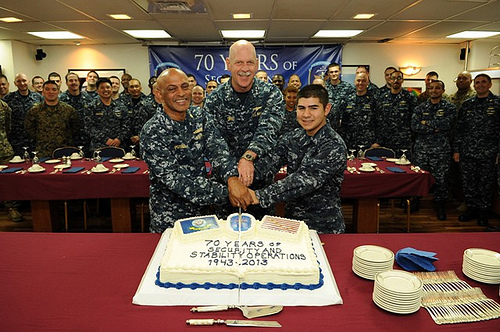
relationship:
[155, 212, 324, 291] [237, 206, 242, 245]
cake cut with knife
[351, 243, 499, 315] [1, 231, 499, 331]
dishes on table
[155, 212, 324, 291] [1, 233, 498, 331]
cake on tablecloth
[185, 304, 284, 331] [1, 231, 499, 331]
knives on table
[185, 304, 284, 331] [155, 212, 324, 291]
knives for cake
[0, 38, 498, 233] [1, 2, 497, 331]
men in photo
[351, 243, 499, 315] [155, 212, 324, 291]
dishes for cake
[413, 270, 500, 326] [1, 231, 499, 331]
forks on table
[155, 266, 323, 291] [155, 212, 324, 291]
icing on cake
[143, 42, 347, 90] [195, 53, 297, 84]
banner with words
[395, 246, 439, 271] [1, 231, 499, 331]
napkin on table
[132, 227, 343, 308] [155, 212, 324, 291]
napkin under cake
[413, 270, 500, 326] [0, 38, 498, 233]
forks for men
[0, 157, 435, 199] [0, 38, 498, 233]
table for men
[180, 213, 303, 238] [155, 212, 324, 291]
images on cake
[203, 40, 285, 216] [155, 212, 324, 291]
man cutting cake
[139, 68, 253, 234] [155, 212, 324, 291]
man cutting cake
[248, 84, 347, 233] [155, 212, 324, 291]
man cutting cake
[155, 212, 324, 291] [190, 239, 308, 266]
cake has lettering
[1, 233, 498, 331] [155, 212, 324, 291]
tablecloth under cake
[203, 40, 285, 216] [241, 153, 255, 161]
man wearing watch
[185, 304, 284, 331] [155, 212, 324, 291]
knives beside cake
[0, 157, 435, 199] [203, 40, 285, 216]
table behind man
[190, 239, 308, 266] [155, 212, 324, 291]
lettering on cake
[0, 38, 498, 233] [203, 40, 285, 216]
men behind man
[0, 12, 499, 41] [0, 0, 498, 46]
lights on ceiling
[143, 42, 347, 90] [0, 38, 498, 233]
banner behind men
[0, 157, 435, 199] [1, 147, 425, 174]
table has settings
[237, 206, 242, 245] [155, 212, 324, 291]
knife cutting cake